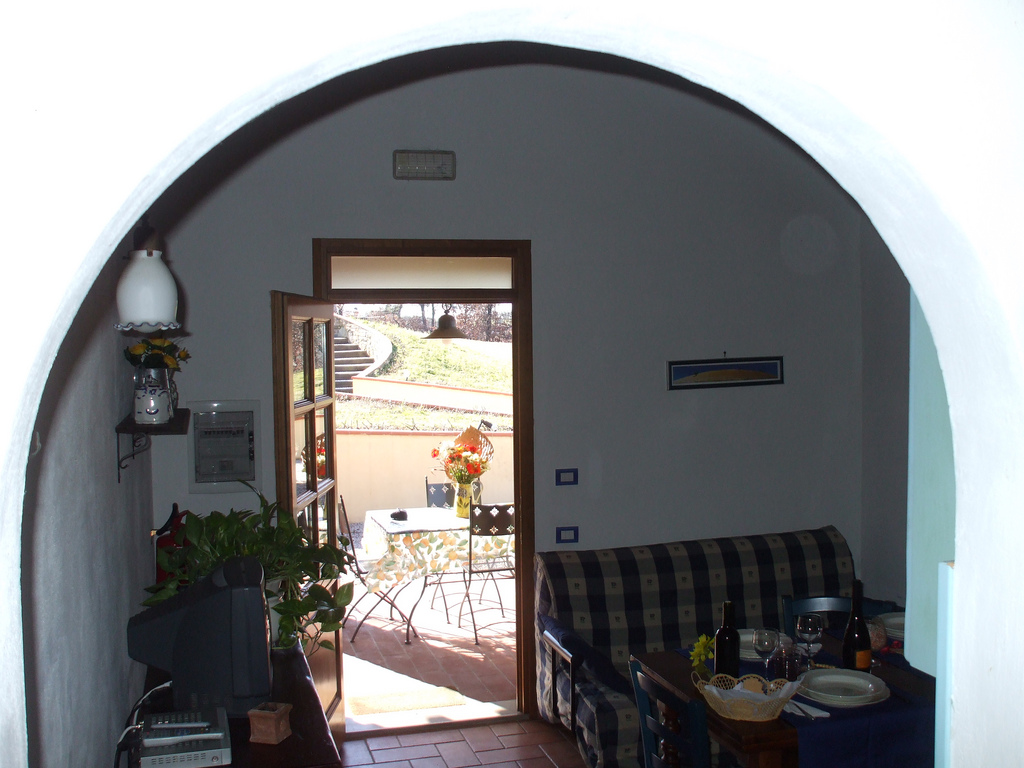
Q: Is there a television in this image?
A: Yes, there is a television.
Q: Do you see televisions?
A: Yes, there is a television.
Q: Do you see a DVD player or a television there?
A: Yes, there is a television.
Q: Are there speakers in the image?
A: No, there are no speakers.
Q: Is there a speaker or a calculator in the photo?
A: No, there are no speakers or calculators.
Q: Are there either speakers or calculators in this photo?
A: No, there are no speakers or calculators.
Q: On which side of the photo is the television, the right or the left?
A: The television is on the left of the image.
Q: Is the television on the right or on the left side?
A: The television is on the left of the image.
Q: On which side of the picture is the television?
A: The television is on the left of the image.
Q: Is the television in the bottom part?
A: Yes, the television is in the bottom of the image.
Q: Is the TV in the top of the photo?
A: No, the TV is in the bottom of the image.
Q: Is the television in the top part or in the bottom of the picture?
A: The television is in the bottom of the image.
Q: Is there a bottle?
A: Yes, there is a bottle.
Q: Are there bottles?
A: Yes, there is a bottle.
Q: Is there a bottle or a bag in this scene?
A: Yes, there is a bottle.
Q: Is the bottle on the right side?
A: Yes, the bottle is on the right of the image.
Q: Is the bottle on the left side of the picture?
A: No, the bottle is on the right of the image.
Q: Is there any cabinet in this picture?
A: No, there are no cabinets.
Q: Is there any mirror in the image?
A: No, there are no mirrors.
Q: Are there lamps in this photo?
A: Yes, there is a lamp.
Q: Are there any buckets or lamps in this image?
A: Yes, there is a lamp.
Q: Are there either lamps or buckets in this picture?
A: Yes, there is a lamp.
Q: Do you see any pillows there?
A: No, there are no pillows.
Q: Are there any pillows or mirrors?
A: No, there are no pillows or mirrors.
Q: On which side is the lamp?
A: The lamp is on the left of the image.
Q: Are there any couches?
A: Yes, there is a couch.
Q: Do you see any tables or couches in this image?
A: Yes, there is a couch.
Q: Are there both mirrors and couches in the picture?
A: No, there is a couch but no mirrors.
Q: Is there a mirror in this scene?
A: No, there are no mirrors.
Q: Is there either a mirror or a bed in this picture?
A: No, there are no mirrors or beds.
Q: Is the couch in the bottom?
A: Yes, the couch is in the bottom of the image.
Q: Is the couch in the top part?
A: No, the couch is in the bottom of the image.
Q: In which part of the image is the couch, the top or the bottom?
A: The couch is in the bottom of the image.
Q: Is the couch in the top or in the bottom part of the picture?
A: The couch is in the bottom of the image.